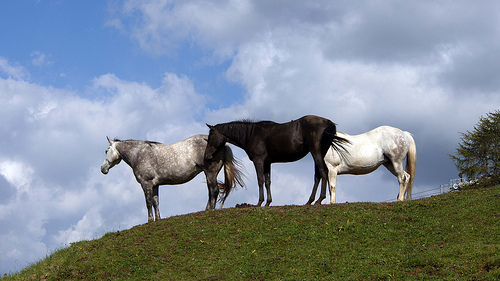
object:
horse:
[201, 116, 350, 206]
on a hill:
[14, 214, 497, 280]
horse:
[99, 130, 244, 219]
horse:
[321, 124, 414, 200]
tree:
[449, 110, 499, 181]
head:
[98, 131, 122, 173]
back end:
[272, 113, 337, 204]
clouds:
[329, 13, 479, 66]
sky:
[3, 3, 172, 83]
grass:
[141, 226, 481, 268]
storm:
[264, 35, 329, 85]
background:
[6, 5, 495, 111]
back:
[323, 126, 431, 201]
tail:
[220, 146, 246, 204]